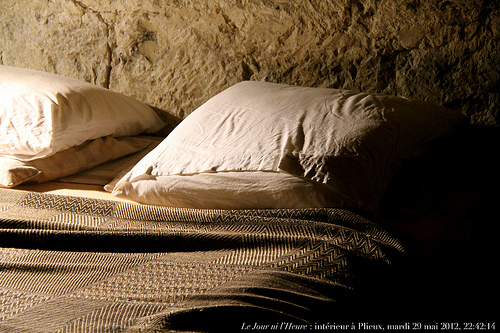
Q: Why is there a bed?
A: For sleeping.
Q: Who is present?
A: No one.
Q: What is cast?
A: Shadow.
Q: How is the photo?
A: Clear.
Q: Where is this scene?
A: In a bedroom.